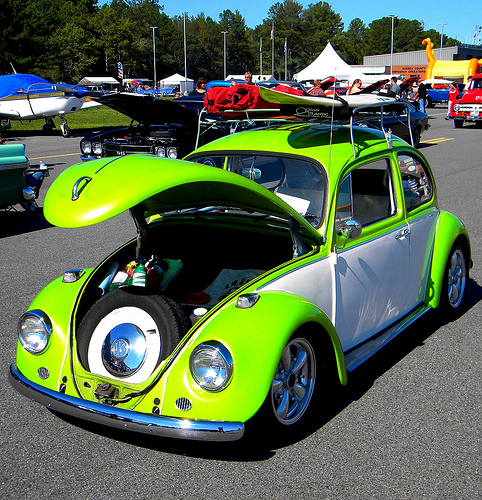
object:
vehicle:
[8, 120, 474, 446]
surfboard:
[256, 84, 396, 109]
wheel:
[78, 282, 181, 388]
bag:
[201, 84, 228, 111]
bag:
[228, 80, 302, 110]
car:
[81, 84, 266, 159]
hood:
[90, 92, 197, 125]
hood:
[41, 151, 325, 239]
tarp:
[0, 71, 89, 98]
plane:
[1, 59, 90, 137]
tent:
[289, 38, 365, 84]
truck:
[448, 70, 480, 125]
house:
[416, 38, 481, 87]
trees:
[2, 0, 457, 82]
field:
[2, 98, 176, 128]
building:
[361, 45, 481, 64]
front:
[6, 155, 323, 457]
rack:
[193, 110, 418, 151]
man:
[242, 67, 255, 84]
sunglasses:
[243, 74, 255, 79]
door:
[332, 222, 427, 351]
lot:
[0, 111, 481, 498]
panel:
[256, 258, 335, 324]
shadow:
[286, 125, 392, 150]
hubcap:
[101, 321, 149, 379]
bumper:
[6, 362, 244, 446]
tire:
[259, 331, 328, 442]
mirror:
[239, 164, 263, 180]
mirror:
[339, 219, 366, 239]